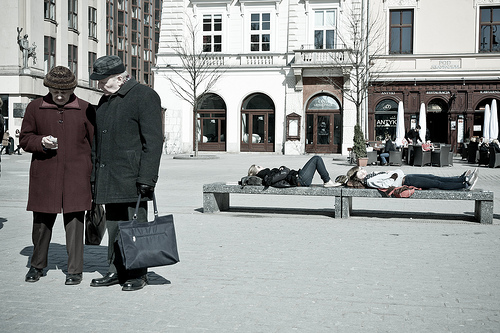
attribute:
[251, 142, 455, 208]
people — laying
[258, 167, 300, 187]
jacket — black 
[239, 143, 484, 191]
people — laying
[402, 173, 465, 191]
pants — dark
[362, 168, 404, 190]
jacket — light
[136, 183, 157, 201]
gloves — black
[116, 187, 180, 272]
satchel — soft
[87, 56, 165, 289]
person — standing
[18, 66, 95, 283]
person — standing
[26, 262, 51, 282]
shoes — black 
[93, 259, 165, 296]
shoes — leather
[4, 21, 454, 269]
people — laying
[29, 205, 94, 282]
pants — brown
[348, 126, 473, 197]
person — laying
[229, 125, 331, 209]
person — laying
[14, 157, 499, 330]
paved area — large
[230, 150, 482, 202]
women — laying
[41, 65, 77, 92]
hat — brown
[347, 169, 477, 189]
people — laying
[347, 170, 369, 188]
hair — long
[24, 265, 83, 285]
shoes — leather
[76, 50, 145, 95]
head — person's